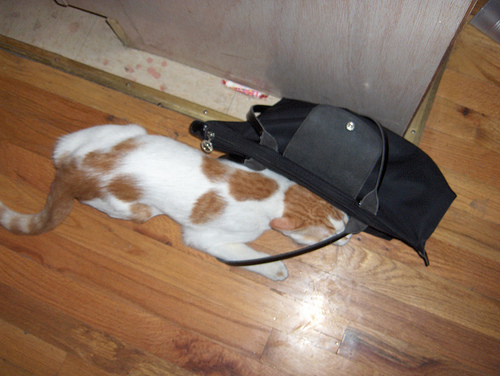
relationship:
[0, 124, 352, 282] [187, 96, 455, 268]
cat near handbag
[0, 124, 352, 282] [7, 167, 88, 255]
cat has tail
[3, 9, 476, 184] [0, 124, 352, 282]
wall next cat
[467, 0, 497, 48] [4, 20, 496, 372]
plastic container on floor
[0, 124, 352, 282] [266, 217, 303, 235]
cat has ear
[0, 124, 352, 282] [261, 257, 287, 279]
cat has paw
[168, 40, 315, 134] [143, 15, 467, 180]
candy by wall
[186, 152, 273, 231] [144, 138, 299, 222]
spots on back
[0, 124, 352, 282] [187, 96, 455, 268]
cat under handbag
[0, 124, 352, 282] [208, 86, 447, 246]
cat under handbag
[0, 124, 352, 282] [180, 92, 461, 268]
cat under lady's handbag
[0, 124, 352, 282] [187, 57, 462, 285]
cat under handbag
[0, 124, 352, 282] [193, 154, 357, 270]
cat laying in handle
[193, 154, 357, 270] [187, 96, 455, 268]
handle of handbag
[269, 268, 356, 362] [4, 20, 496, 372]
reflection in floor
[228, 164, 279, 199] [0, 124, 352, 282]
brown spot on cat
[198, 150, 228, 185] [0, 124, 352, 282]
brown spot on cat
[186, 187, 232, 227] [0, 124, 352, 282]
spots on cat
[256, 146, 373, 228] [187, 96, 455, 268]
zipper on handbag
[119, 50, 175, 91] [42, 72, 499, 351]
spots on floor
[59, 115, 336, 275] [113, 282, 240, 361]
cat laying on floor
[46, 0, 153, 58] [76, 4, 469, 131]
edge of cabinet